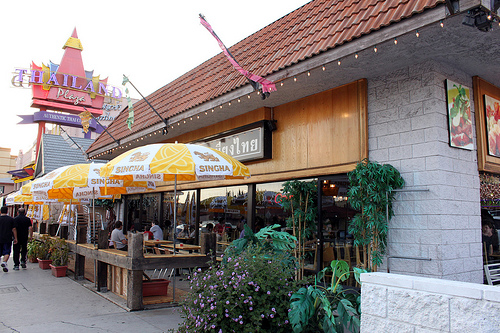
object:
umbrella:
[99, 138, 250, 256]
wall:
[360, 272, 500, 332]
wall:
[367, 61, 482, 286]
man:
[14, 209, 34, 272]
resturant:
[0, 139, 252, 309]